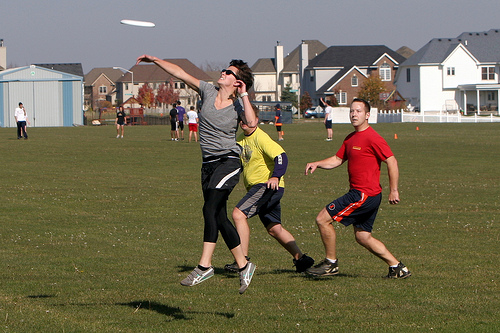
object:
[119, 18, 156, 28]
fridbie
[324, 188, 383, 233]
shorts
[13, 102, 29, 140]
person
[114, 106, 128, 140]
person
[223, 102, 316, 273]
people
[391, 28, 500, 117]
house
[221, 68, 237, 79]
glasses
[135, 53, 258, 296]
lady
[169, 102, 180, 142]
person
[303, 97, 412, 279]
man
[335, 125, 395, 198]
red shirt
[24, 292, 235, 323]
shadow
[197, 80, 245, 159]
shirt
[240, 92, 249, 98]
bracelet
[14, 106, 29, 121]
shirt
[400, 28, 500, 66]
roof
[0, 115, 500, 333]
field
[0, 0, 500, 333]
air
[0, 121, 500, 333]
ground